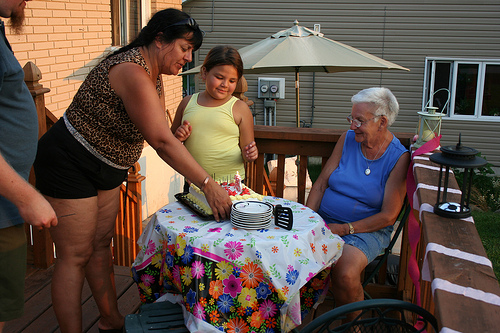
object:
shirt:
[181, 92, 244, 186]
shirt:
[61, 49, 160, 170]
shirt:
[317, 130, 411, 235]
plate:
[230, 196, 272, 228]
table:
[153, 194, 326, 270]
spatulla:
[271, 203, 295, 231]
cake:
[185, 180, 262, 215]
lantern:
[429, 135, 486, 221]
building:
[183, 0, 499, 165]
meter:
[256, 78, 285, 108]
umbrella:
[177, 20, 410, 75]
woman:
[34, 9, 232, 332]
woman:
[304, 86, 411, 333]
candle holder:
[431, 134, 488, 219]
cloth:
[131, 193, 345, 331]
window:
[421, 56, 498, 121]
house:
[2, 0, 182, 129]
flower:
[223, 240, 242, 260]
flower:
[241, 262, 264, 288]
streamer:
[408, 135, 446, 331]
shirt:
[0, 22, 40, 229]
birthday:
[213, 172, 244, 195]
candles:
[214, 175, 248, 193]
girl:
[170, 45, 259, 195]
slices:
[246, 192, 263, 206]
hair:
[351, 88, 402, 124]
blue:
[316, 128, 410, 237]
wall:
[0, 0, 184, 143]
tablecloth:
[130, 194, 345, 332]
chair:
[285, 296, 441, 333]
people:
[1, 1, 410, 331]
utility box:
[257, 77, 286, 126]